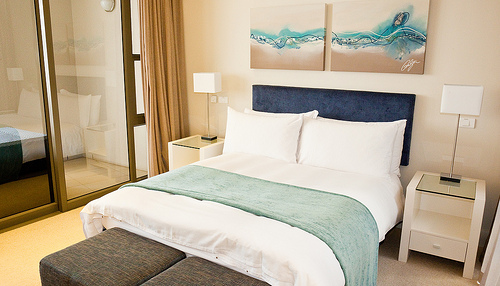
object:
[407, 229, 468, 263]
drawer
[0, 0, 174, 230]
door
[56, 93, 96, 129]
pillows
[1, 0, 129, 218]
glass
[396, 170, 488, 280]
table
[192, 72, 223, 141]
lamp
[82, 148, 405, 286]
white cover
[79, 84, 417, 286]
bed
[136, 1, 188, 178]
beige curtain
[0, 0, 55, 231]
windows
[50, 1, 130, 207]
panels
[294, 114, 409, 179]
pillow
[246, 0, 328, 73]
paintings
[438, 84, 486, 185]
lamp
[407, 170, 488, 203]
table top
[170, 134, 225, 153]
table top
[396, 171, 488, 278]
stand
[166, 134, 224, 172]
stand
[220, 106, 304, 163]
pillow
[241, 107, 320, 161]
white pillow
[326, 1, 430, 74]
paintings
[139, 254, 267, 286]
ottomans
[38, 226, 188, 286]
bench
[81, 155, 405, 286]
blanket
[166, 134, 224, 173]
night stand